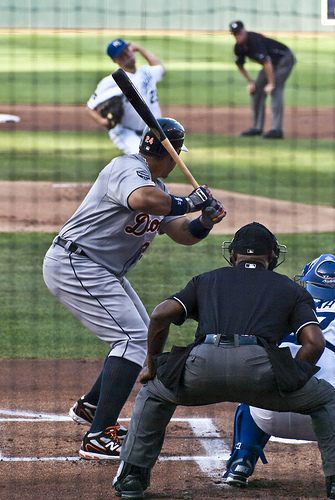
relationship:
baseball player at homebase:
[42, 118, 224, 459] [49, 110, 333, 391]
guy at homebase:
[106, 215, 330, 496] [49, 110, 333, 391]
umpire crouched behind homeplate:
[218, 5, 284, 125] [263, 428, 319, 448]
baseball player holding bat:
[42, 118, 224, 459] [110, 62, 216, 194]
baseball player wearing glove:
[42, 118, 224, 459] [184, 184, 212, 211]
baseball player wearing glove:
[42, 118, 224, 459] [199, 196, 225, 225]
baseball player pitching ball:
[86, 37, 166, 157] [122, 37, 134, 53]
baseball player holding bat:
[42, 118, 224, 459] [108, 64, 227, 217]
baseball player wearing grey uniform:
[42, 118, 224, 459] [41, 154, 186, 366]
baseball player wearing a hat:
[86, 37, 166, 157] [106, 37, 127, 57]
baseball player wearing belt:
[86, 37, 166, 157] [117, 120, 170, 145]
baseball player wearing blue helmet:
[42, 118, 224, 459] [136, 113, 188, 159]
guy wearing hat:
[112, 224, 335, 500] [227, 219, 277, 253]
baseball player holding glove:
[86, 37, 166, 157] [101, 96, 124, 130]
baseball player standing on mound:
[86, 37, 166, 157] [225, 189, 293, 221]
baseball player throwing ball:
[86, 37, 166, 157] [125, 36, 132, 54]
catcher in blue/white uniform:
[220, 249, 333, 485] [234, 297, 334, 458]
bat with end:
[94, 70, 217, 210] [108, 68, 171, 140]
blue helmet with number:
[139, 118, 188, 156] [140, 129, 149, 144]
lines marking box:
[0, 410, 234, 462] [3, 381, 236, 469]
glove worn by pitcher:
[99, 96, 124, 129] [84, 39, 167, 152]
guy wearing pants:
[112, 224, 335, 500] [119, 331, 334, 476]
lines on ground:
[1, 405, 241, 485] [1, 131, 333, 496]